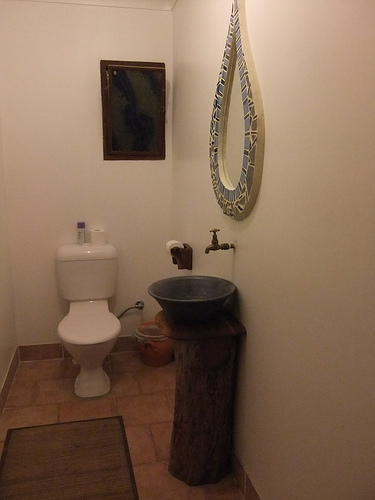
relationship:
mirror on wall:
[203, 19, 286, 231] [161, 13, 363, 325]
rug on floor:
[29, 412, 132, 499] [33, 342, 194, 499]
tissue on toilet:
[89, 226, 109, 251] [47, 247, 138, 412]